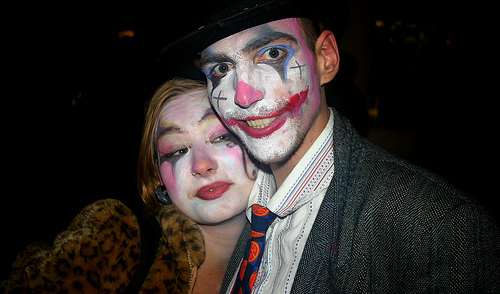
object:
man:
[165, 0, 499, 294]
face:
[196, 17, 321, 165]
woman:
[1, 74, 264, 294]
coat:
[0, 196, 210, 294]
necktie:
[227, 201, 279, 294]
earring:
[153, 183, 173, 206]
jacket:
[213, 105, 500, 293]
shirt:
[225, 106, 340, 294]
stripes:
[311, 160, 336, 192]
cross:
[288, 60, 306, 79]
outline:
[255, 42, 296, 80]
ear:
[314, 30, 340, 85]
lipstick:
[217, 84, 310, 141]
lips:
[234, 114, 289, 137]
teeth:
[242, 115, 280, 130]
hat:
[157, 0, 324, 59]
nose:
[232, 61, 266, 110]